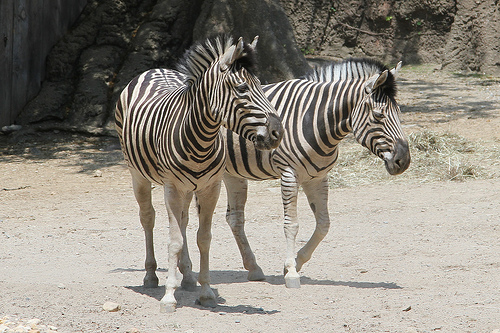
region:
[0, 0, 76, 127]
a wooden fence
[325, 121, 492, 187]
a pile of dry grass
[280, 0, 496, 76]
a large stone wall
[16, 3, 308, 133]
a large boulder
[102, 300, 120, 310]
a rock in the dirt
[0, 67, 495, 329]
a large dirt landscape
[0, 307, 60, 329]
a small group of rocks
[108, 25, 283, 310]
A zebra walking in dirt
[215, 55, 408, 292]
A zebra walking in dirt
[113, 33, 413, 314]
a pair of zebras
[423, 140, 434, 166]
edge of a bush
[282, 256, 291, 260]
edge of a leg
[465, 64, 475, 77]
part of a rock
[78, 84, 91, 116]
edge of a rock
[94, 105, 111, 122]
side of a rock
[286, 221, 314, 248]
part of a zebra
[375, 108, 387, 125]
eye of a zebra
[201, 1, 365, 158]
the head of a zebra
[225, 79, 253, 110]
the eye of a zebra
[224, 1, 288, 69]
the ear of a zebra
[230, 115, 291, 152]
the nose of a zebra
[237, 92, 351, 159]
the mouth of a zebra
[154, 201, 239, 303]
the front legs of a zebra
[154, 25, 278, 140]
the main of a zebra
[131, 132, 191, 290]
the back leg of a zebra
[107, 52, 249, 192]
the body of a zebra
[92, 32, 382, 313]
a zebra on the ground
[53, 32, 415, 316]
two zebras together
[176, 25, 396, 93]
both zebras have longish manes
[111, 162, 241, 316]
this zebra has no stripes on his legs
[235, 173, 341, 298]
this zebra has few stripes on his legs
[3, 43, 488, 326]
the area is totally barren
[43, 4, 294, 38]
big rocks are in the background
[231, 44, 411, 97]
they have short forelocks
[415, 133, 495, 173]
hay is on the ground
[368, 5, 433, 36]
some greenery is in the background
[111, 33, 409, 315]
two zebras walking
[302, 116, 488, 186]
hay for the zebras to eat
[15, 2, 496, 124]
stone walls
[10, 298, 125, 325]
rocks on the ground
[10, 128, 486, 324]
dry dirt ground covering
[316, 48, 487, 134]
shadow of tree on the ground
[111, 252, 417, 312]
shadows of zebras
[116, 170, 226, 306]
zebras legs don't have stripes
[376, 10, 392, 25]
green leaves on the wall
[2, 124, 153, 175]
shadow of trees on the ground